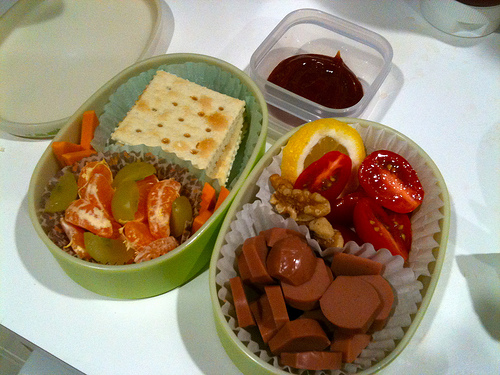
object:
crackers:
[109, 69, 246, 184]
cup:
[209, 118, 455, 374]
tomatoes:
[358, 150, 425, 214]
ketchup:
[264, 49, 363, 119]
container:
[242, 7, 393, 122]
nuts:
[268, 174, 333, 223]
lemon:
[281, 117, 366, 191]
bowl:
[30, 51, 270, 300]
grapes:
[43, 156, 193, 266]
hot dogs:
[228, 226, 395, 372]